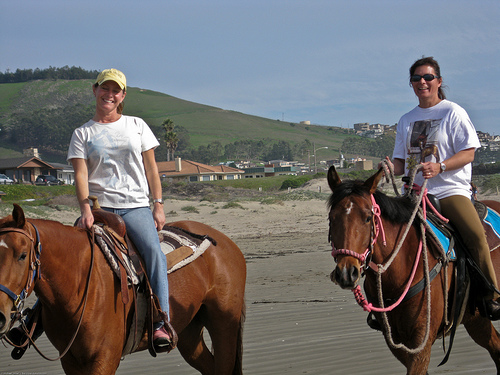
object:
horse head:
[323, 165, 384, 290]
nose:
[332, 264, 361, 283]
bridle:
[0, 223, 96, 362]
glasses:
[410, 74, 439, 82]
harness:
[0, 202, 42, 336]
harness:
[327, 163, 383, 289]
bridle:
[333, 165, 443, 353]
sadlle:
[73, 209, 125, 253]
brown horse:
[1, 202, 247, 375]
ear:
[327, 164, 342, 192]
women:
[377, 55, 498, 319]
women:
[64, 67, 175, 348]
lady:
[388, 56, 500, 319]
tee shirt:
[392, 99, 484, 201]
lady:
[66, 67, 173, 346]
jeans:
[99, 206, 170, 326]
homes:
[1, 154, 54, 183]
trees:
[2, 63, 88, 82]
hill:
[0, 74, 338, 166]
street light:
[310, 142, 328, 174]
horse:
[326, 165, 500, 368]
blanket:
[94, 213, 219, 285]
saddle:
[75, 208, 216, 355]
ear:
[363, 166, 384, 193]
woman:
[66, 67, 194, 295]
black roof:
[1, 151, 54, 168]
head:
[0, 201, 31, 335]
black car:
[34, 174, 61, 186]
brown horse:
[326, 164, 500, 375]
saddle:
[403, 180, 500, 319]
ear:
[11, 202, 26, 226]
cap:
[95, 68, 127, 92]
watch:
[153, 199, 164, 204]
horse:
[0, 202, 247, 375]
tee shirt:
[64, 115, 160, 210]